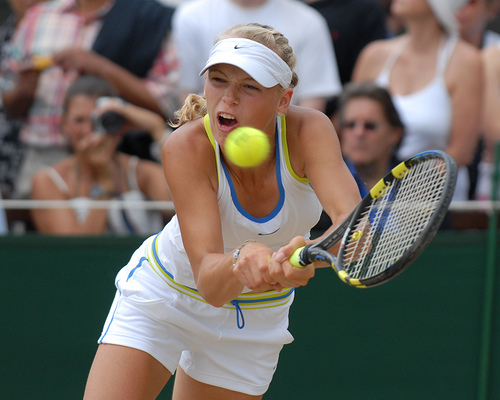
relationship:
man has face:
[37, 0, 187, 68] [345, 100, 396, 161]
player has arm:
[82, 22, 374, 399] [154, 178, 256, 267]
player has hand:
[82, 22, 374, 399] [229, 221, 286, 305]